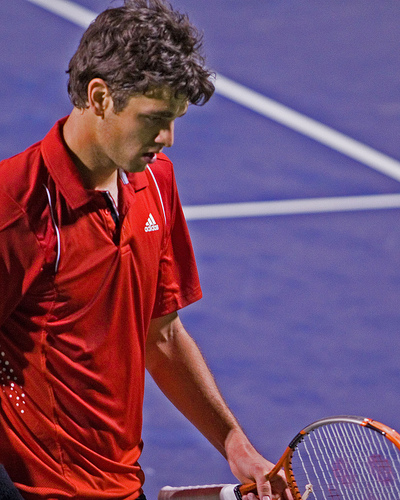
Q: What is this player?
A: Tennis.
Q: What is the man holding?
A: A racket.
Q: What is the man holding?
A: Tennis racket.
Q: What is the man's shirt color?
A: Orange.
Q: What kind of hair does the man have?
A: Dark hair.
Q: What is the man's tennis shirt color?
A: Red.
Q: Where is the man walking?
A: Tennis court.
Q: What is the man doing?
A: Playing tennis.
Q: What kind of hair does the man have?
A: Curly hair.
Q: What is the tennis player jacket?
A: Black red and white.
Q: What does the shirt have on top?
A: Collar.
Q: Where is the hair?
A: On the man.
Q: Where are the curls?
A: On the man.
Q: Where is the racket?
A: In the hand.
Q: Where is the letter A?
A: On the shirt.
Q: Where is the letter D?
A: On the shirt.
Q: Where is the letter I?
A: On the shirt.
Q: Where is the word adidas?
A: On the shirt.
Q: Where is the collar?
A: On the shirt.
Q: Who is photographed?
A: A man.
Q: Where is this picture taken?
A: On the tennis court.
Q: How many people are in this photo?
A: One.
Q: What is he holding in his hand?
A: A racket.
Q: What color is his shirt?
A: Red.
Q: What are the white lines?
A: In bound lines.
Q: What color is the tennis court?
A: Purple.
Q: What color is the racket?
A: Red.